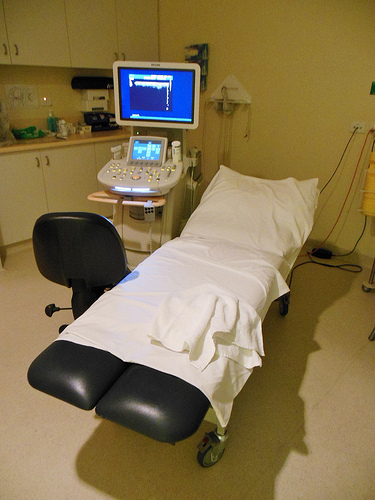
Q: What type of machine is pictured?
A: Ultrasound.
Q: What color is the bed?
A: Blue.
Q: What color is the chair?
A: Black.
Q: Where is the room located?
A: Medical center.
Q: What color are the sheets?
A: White.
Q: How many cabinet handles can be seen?
A: Six.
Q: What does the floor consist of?
A: Tile.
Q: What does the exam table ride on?
A: Wheels.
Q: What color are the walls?
A: White.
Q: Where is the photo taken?
A: Doctor's office.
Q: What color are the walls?
A: White.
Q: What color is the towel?
A: White.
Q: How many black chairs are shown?
A: 1.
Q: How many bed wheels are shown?
A: 2.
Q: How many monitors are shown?
A: 2.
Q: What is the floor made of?
A: Tiles.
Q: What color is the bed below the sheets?
A: Black.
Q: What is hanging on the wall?
A: Cabinets.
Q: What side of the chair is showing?
A: The back.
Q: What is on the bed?
A: Towel.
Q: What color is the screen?
A: Blue.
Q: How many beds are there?
A: 1.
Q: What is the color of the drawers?
A: White.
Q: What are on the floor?
A: Cables.